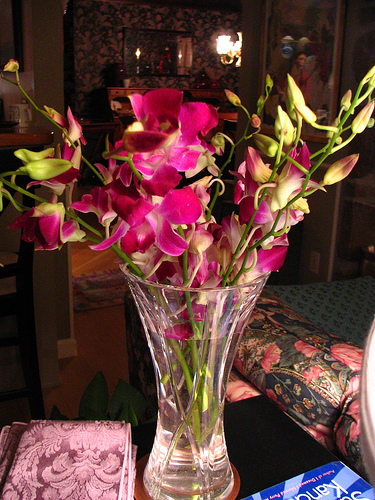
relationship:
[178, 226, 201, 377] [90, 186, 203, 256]
stem on flower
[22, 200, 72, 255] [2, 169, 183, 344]
flower on a stem